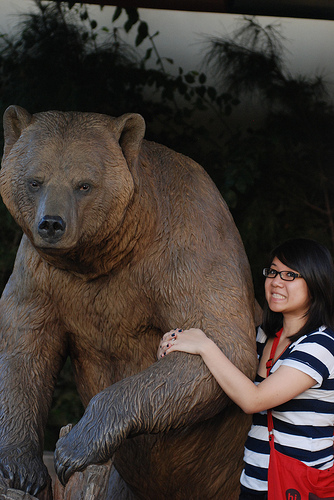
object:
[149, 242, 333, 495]
girl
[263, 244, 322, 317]
head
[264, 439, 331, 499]
bag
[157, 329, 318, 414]
arm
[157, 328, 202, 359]
hand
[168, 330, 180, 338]
finger nail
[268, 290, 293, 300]
mouth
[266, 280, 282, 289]
nose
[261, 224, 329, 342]
hair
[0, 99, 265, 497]
bear statue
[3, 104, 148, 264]
head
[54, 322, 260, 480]
arm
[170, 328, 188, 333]
nail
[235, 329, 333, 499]
shirt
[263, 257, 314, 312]
face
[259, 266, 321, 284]
glasses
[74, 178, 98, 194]
eye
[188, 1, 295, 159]
bushes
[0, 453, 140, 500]
log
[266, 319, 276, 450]
strap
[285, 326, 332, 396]
shoulder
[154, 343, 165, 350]
fingernail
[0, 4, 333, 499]
background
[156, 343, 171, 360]
nail polish